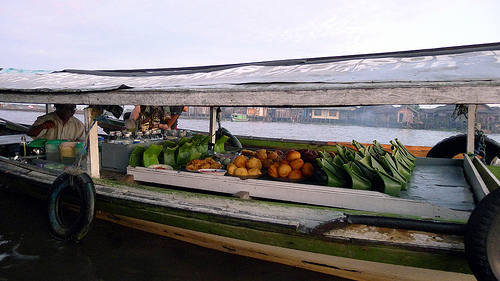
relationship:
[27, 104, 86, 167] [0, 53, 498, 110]
man under roof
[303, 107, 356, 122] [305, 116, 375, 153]
building along water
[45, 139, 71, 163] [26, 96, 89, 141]
container by man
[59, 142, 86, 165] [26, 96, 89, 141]
container by man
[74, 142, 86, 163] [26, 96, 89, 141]
container by man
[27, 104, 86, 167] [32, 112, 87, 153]
man wearing shirt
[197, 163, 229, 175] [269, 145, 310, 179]
bowl of fruits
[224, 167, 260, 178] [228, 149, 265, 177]
bowl of fruits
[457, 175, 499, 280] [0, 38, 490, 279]
tire on boat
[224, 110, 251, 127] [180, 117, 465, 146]
boat across water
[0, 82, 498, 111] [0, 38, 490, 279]
roof of boat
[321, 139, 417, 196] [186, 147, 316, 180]
bags beside fruit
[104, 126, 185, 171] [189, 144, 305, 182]
bottles beside fruit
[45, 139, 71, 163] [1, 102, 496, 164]
container beside water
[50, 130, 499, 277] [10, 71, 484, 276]
tires attached to boat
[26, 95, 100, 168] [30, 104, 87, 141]
man wearing shirt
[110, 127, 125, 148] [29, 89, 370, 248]
bottles on boat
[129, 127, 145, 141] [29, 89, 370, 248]
bottles on boat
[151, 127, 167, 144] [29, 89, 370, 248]
bottles on boat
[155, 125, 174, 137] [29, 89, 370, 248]
bottles on boat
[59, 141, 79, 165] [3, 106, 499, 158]
container by water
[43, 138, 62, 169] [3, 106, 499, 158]
container by water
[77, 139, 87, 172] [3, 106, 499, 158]
container by water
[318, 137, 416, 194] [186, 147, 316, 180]
bags by fruit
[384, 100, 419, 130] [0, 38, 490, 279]
building behind boat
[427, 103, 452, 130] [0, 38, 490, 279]
building behind boat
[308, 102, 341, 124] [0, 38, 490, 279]
building behind boat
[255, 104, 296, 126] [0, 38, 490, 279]
building behind boat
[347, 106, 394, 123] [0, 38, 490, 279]
building behind boat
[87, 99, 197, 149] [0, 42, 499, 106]
people under boat canopy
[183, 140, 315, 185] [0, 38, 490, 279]
fruit on boat